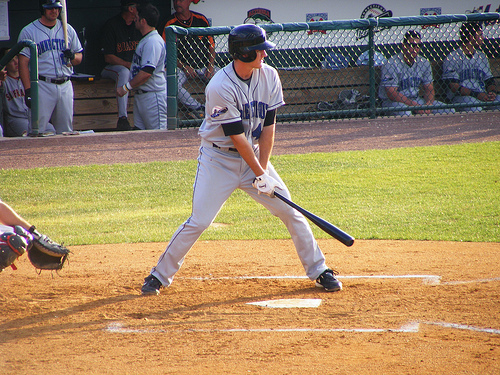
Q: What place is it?
A: It is a field.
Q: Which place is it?
A: It is a field.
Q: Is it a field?
A: Yes, it is a field.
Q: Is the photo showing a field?
A: Yes, it is showing a field.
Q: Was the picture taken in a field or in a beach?
A: It was taken at a field.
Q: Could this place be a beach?
A: No, it is a field.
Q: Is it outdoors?
A: Yes, it is outdoors.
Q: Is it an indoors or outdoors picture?
A: It is outdoors.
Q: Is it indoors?
A: No, it is outdoors.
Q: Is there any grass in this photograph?
A: Yes, there is grass.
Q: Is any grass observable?
A: Yes, there is grass.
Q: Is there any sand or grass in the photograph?
A: Yes, there is grass.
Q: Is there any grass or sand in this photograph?
A: Yes, there is grass.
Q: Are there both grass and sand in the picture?
A: Yes, there are both grass and sand.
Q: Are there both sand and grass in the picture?
A: Yes, there are both grass and sand.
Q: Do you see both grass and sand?
A: Yes, there are both grass and sand.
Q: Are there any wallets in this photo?
A: No, there are no wallets.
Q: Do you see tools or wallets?
A: No, there are no wallets or tools.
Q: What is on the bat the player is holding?
A: The cap is on the bat.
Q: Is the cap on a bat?
A: Yes, the cap is on a bat.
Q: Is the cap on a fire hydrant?
A: No, the cap is on a bat.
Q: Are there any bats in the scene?
A: Yes, there is a bat.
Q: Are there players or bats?
A: Yes, there is a bat.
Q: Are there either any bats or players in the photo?
A: Yes, there is a bat.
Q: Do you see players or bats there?
A: Yes, there is a bat.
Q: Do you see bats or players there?
A: Yes, there is a bat.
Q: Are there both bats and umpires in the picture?
A: No, there is a bat but no umpires.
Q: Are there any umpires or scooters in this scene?
A: No, there are no umpires or scooters.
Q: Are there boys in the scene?
A: No, there are no boys.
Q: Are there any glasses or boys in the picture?
A: No, there are no boys or glasses.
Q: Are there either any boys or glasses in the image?
A: No, there are no boys or glasses.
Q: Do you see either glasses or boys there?
A: No, there are no boys or glasses.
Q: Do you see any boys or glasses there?
A: No, there are no boys or glasses.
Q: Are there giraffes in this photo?
A: No, there are no giraffes.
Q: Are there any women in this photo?
A: No, there are no women.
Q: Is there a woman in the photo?
A: No, there are no women.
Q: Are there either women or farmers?
A: No, there are no women or farmers.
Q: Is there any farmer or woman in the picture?
A: No, there are no women or farmers.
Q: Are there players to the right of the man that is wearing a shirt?
A: Yes, there is a player to the right of the man.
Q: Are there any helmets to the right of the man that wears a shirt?
A: No, there is a player to the right of the man.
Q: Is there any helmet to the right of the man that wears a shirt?
A: No, there is a player to the right of the man.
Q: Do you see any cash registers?
A: No, there are no cash registers.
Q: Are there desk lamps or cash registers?
A: No, there are no cash registers or desk lamps.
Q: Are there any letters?
A: Yes, there are letters.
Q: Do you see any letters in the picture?
A: Yes, there are letters.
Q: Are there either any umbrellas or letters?
A: Yes, there are letters.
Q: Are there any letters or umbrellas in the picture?
A: Yes, there are letters.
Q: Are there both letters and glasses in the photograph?
A: No, there are letters but no glasses.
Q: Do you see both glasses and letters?
A: No, there are letters but no glasses.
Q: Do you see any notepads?
A: No, there are no notepads.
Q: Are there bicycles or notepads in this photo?
A: No, there are no notepads or bicycles.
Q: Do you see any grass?
A: Yes, there is grass.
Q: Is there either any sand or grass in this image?
A: Yes, there is grass.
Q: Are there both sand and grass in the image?
A: Yes, there are both grass and sand.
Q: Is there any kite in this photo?
A: No, there are no kites.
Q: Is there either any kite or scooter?
A: No, there are no kites or scooters.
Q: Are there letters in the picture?
A: Yes, there are letters.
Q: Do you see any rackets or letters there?
A: Yes, there are letters.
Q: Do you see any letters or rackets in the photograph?
A: Yes, there are letters.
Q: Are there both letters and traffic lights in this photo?
A: No, there are letters but no traffic lights.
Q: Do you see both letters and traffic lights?
A: No, there are letters but no traffic lights.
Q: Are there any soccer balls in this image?
A: No, there are no soccer balls.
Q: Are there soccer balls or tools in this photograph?
A: No, there are no soccer balls or tools.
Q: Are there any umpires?
A: No, there are no umpires.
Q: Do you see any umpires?
A: No, there are no umpires.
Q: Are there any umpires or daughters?
A: No, there are no umpires or daughters.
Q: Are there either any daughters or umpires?
A: No, there are no umpires or daughters.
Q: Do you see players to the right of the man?
A: Yes, there is a player to the right of the man.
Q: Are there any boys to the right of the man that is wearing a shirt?
A: No, there is a player to the right of the man.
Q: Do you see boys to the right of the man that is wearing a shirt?
A: No, there is a player to the right of the man.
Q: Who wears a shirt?
A: The player wears a shirt.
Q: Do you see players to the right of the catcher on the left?
A: Yes, there is a player to the right of the catcher.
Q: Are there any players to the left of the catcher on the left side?
A: No, the player is to the right of the catcher.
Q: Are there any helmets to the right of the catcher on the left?
A: No, there is a player to the right of the catcher.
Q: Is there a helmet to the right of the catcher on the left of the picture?
A: No, there is a player to the right of the catcher.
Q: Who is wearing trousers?
A: The player is wearing trousers.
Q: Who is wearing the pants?
A: The player is wearing trousers.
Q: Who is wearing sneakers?
A: The player is wearing sneakers.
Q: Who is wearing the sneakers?
A: The player is wearing sneakers.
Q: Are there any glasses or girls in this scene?
A: No, there are no girls or glasses.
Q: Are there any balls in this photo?
A: No, there are no balls.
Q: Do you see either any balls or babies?
A: No, there are no balls or babies.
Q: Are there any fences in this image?
A: Yes, there is a fence.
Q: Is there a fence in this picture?
A: Yes, there is a fence.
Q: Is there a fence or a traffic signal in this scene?
A: Yes, there is a fence.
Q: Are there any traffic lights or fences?
A: Yes, there is a fence.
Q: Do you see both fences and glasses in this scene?
A: No, there is a fence but no glasses.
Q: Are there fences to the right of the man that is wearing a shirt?
A: Yes, there is a fence to the right of the man.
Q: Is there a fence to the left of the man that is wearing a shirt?
A: No, the fence is to the right of the man.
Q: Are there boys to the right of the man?
A: No, there is a fence to the right of the man.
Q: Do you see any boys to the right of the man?
A: No, there is a fence to the right of the man.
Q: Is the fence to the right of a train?
A: No, the fence is to the right of the man.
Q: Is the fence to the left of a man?
A: No, the fence is to the right of a man.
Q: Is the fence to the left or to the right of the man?
A: The fence is to the right of the man.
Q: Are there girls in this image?
A: No, there are no girls.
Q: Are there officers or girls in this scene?
A: No, there are no girls or officers.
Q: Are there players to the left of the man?
A: Yes, there is a player to the left of the man.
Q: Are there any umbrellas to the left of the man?
A: No, there is a player to the left of the man.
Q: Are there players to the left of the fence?
A: Yes, there is a player to the left of the fence.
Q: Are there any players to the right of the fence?
A: No, the player is to the left of the fence.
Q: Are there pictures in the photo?
A: No, there are no pictures.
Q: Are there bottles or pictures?
A: No, there are no pictures or bottles.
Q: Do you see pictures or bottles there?
A: No, there are no pictures or bottles.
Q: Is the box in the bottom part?
A: Yes, the box is in the bottom of the image.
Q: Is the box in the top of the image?
A: No, the box is in the bottom of the image.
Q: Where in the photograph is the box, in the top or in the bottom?
A: The box is in the bottom of the image.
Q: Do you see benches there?
A: Yes, there is a bench.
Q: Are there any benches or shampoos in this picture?
A: Yes, there is a bench.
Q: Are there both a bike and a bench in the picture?
A: No, there is a bench but no bikes.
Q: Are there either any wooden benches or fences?
A: Yes, there is a wood bench.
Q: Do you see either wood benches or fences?
A: Yes, there is a wood bench.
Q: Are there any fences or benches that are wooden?
A: Yes, the bench is wooden.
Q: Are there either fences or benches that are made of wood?
A: Yes, the bench is made of wood.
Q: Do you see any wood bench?
A: Yes, there is a bench that is made of wood.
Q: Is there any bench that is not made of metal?
A: Yes, there is a bench that is made of wood.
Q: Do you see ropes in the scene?
A: No, there are no ropes.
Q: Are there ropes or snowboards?
A: No, there are no ropes or snowboards.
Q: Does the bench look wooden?
A: Yes, the bench is wooden.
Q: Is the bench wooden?
A: Yes, the bench is wooden.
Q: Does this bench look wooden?
A: Yes, the bench is wooden.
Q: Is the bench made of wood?
A: Yes, the bench is made of wood.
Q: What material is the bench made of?
A: The bench is made of wood.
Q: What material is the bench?
A: The bench is made of wood.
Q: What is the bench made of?
A: The bench is made of wood.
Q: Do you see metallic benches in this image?
A: No, there is a bench but it is wooden.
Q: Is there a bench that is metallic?
A: No, there is a bench but it is wooden.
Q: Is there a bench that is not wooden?
A: No, there is a bench but it is wooden.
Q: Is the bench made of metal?
A: No, the bench is made of wood.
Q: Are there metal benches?
A: No, there is a bench but it is made of wood.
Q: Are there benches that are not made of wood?
A: No, there is a bench but it is made of wood.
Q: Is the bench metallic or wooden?
A: The bench is wooden.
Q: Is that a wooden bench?
A: Yes, that is a wooden bench.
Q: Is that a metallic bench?
A: No, that is a wooden bench.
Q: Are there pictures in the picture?
A: No, there are no pictures.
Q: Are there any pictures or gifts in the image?
A: No, there are no pictures or gifts.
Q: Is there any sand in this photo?
A: Yes, there is sand.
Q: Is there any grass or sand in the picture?
A: Yes, there is sand.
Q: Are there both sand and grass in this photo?
A: Yes, there are both sand and grass.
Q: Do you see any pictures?
A: No, there are no pictures.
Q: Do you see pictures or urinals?
A: No, there are no pictures or urinals.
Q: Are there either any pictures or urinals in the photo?
A: No, there are no pictures or urinals.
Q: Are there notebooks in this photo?
A: No, there are no notebooks.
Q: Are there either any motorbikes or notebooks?
A: No, there are no notebooks or motorbikes.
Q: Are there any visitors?
A: No, there are no visitors.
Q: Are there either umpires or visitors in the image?
A: No, there are no visitors or umpires.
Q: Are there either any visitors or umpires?
A: No, there are no visitors or umpires.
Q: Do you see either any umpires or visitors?
A: No, there are no visitors or umpires.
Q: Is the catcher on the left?
A: Yes, the catcher is on the left of the image.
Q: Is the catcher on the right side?
A: No, the catcher is on the left of the image.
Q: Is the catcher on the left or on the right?
A: The catcher is on the left of the image.